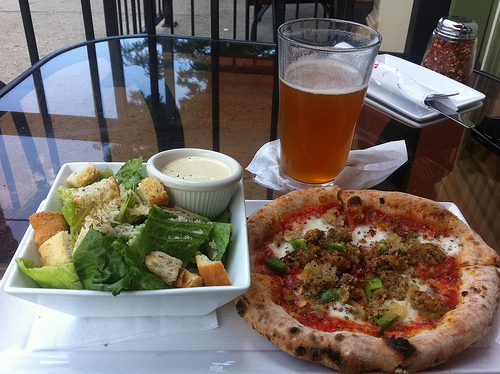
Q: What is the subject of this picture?
A: Meal.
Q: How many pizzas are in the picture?
A: One.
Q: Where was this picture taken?
A: Restaurant.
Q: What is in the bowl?
A: Salad.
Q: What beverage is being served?
A: Beer.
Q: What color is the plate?
A: White.